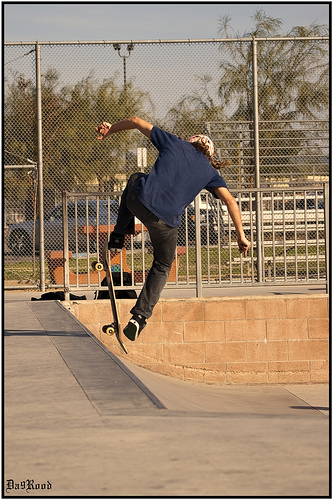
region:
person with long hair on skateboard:
[67, 92, 213, 351]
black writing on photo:
[8, 467, 60, 492]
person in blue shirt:
[137, 107, 227, 237]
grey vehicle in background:
[11, 180, 139, 263]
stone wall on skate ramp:
[68, 296, 321, 395]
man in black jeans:
[105, 180, 171, 336]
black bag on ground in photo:
[75, 261, 168, 306]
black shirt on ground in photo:
[36, 277, 86, 314]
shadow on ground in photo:
[3, 304, 103, 357]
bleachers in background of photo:
[196, 163, 317, 284]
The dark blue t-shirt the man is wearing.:
[138, 124, 226, 220]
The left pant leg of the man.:
[119, 166, 140, 248]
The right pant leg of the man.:
[135, 220, 168, 317]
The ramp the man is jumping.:
[49, 292, 327, 471]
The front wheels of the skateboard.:
[90, 262, 104, 274]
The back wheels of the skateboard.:
[100, 318, 114, 338]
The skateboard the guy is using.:
[100, 237, 132, 353]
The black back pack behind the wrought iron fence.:
[96, 268, 141, 302]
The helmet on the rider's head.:
[186, 123, 214, 151]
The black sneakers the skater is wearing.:
[109, 234, 149, 341]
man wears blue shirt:
[136, 125, 248, 237]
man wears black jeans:
[102, 181, 175, 337]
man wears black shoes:
[107, 226, 146, 355]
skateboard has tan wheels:
[95, 251, 114, 338]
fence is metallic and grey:
[51, 179, 331, 299]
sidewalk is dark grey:
[15, 301, 330, 494]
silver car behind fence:
[27, 205, 135, 242]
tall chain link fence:
[17, 88, 327, 285]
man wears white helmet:
[184, 119, 214, 154]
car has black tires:
[2, 233, 28, 254]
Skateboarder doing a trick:
[86, 107, 263, 372]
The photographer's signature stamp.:
[2, 472, 60, 492]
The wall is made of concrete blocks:
[59, 290, 331, 394]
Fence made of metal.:
[57, 175, 331, 312]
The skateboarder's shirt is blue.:
[128, 127, 222, 237]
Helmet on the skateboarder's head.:
[175, 120, 226, 159]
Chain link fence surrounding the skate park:
[13, 26, 331, 288]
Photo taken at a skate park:
[26, 21, 323, 493]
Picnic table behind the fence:
[22, 207, 197, 277]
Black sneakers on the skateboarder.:
[101, 228, 156, 347]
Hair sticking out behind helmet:
[187, 136, 226, 171]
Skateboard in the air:
[90, 233, 130, 356]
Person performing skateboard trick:
[93, 113, 253, 355]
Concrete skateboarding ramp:
[45, 299, 327, 418]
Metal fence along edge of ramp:
[60, 178, 329, 292]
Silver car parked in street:
[5, 193, 120, 253]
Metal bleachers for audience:
[203, 118, 330, 277]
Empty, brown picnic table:
[43, 219, 188, 285]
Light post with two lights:
[111, 40, 139, 107]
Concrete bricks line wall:
[67, 291, 329, 387]